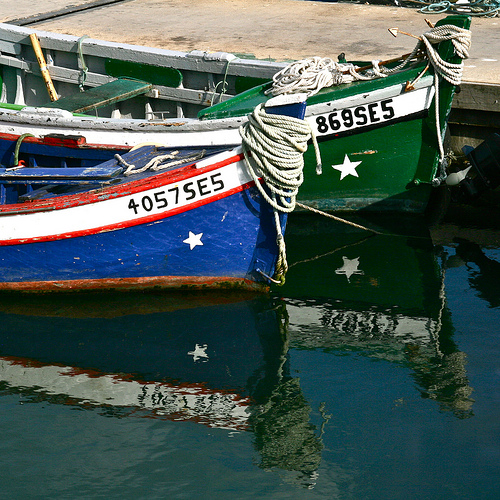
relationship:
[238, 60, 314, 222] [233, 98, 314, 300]
rope around stern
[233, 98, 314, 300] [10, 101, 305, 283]
stern of boat